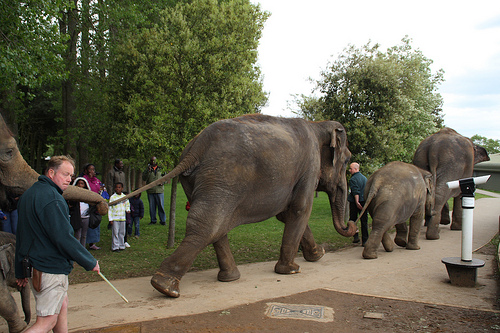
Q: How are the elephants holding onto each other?
A: With their trunks.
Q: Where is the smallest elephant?
A: Second in line.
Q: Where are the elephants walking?
A: Down a sidewalk.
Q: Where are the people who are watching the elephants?
A: Standing on the grass.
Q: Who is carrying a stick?
A: The man in shorts walking by the 4th elephant.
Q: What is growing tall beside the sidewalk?
A: Trees.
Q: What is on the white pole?
A: A telescope.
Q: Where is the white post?
A: By the sidewalk.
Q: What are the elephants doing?
A: Parading.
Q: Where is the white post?
A: To the right.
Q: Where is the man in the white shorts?
A: Next to the elephants.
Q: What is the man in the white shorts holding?
A: A stick.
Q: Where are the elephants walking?
A: The walkway.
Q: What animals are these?
A: Elephant.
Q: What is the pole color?
A: White.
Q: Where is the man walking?
A: Beside elephant.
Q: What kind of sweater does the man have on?
A: Blue sweater.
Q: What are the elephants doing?
A: Walking.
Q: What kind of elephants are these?
A: Asian.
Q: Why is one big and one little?
A: Because it's mother and child elephant.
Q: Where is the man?
A: Behind elephant.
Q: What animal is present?
A: Elephant.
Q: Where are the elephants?
A: Zoo.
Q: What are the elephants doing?
A: Walking.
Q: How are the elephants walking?
A: In a line.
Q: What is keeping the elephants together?
A: Elephant tail.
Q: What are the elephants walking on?
A: Sidewalk.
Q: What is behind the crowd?
A: Trees.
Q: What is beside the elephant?
A: Telescope.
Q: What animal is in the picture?
A: Elephants.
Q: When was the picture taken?
A: During the day.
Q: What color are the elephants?
A: Brown.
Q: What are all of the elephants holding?
A: Another elephants tail.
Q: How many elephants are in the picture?
A: Four.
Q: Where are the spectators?
A: On the grass.